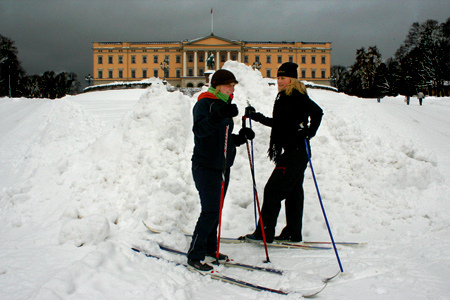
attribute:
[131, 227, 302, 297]
ski — red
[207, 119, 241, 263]
pole — bright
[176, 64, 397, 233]
black outfits — warm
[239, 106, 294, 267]
ski pole — black-and-red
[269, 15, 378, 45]
sky — gray, purple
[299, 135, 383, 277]
pole — red, bright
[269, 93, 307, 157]
sweater — black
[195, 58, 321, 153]
women — red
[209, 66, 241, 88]
cap — black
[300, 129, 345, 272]
ski pole — long, blue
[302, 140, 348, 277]
pole — blue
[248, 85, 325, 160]
jacket — black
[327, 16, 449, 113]
trees — tall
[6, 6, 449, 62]
sky — dark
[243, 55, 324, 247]
female skier — black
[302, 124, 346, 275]
ski pole — bright, blue